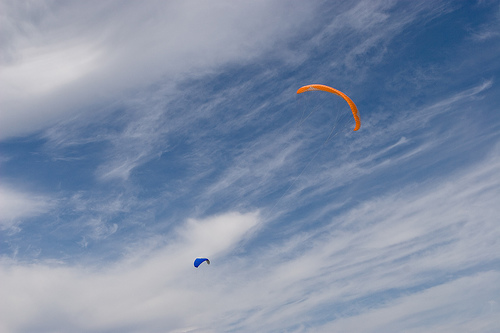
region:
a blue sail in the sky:
[172, 250, 228, 280]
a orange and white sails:
[292, 66, 367, 142]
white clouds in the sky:
[35, 0, 231, 145]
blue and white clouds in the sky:
[396, 1, 481, 86]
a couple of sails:
[155, 66, 395, 276]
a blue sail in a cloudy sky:
[160, 210, 240, 290]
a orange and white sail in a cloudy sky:
[290, 70, 375, 145]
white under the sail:
[298, 82, 323, 102]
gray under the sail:
[201, 255, 206, 266]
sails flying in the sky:
[183, 64, 374, 297]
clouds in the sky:
[1, 3, 497, 328]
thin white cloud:
[94, 158, 165, 186]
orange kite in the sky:
[297, 76, 369, 145]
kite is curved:
[291, 74, 369, 145]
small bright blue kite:
[190, 253, 212, 271]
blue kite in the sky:
[189, 253, 211, 269]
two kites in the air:
[147, 47, 394, 305]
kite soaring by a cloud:
[189, 249, 216, 276]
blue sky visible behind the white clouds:
[1, 1, 494, 331]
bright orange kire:
[289, 78, 381, 146]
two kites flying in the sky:
[103, 48, 422, 302]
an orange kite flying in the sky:
[280, 55, 378, 132]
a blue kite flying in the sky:
[171, 237, 223, 279]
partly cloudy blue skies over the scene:
[385, 29, 464, 139]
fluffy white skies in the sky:
[33, 200, 148, 309]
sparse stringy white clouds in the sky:
[127, 116, 319, 218]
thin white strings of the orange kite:
[234, 103, 346, 234]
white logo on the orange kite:
[299, 83, 327, 93]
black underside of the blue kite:
[201, 257, 212, 265]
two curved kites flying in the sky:
[174, 80, 359, 278]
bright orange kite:
[293, 69, 365, 139]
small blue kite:
[190, 251, 215, 271]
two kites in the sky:
[139, 58, 401, 296]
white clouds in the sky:
[0, 2, 492, 332]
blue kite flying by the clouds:
[187, 251, 223, 279]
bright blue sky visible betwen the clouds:
[1, 1, 493, 326]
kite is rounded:
[293, 71, 368, 143]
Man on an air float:
[192, 83, 362, 275]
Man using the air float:
[191, 256, 213, 273]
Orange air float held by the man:
[290, 78, 365, 136]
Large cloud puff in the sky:
[2, 5, 332, 130]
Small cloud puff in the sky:
[2, 179, 62, 230]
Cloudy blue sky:
[4, 3, 498, 330]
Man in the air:
[192, 256, 217, 273]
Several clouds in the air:
[0, 3, 498, 328]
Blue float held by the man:
[190, 255, 207, 272]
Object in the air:
[192, 81, 359, 276]